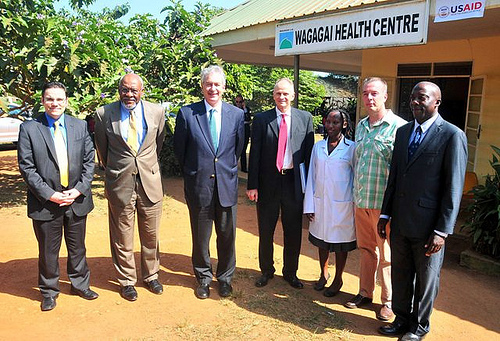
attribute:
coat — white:
[305, 130, 362, 258]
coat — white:
[301, 128, 358, 246]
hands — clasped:
[41, 185, 84, 207]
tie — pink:
[274, 112, 292, 169]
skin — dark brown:
[320, 115, 355, 295]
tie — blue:
[206, 104, 218, 150]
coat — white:
[302, 132, 355, 242]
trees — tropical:
[1, 1, 216, 113]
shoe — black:
[41, 297, 54, 311]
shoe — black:
[70, 286, 98, 298]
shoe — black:
[119, 285, 136, 302]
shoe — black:
[148, 281, 164, 293]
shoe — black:
[194, 282, 209, 298]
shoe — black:
[214, 280, 232, 293]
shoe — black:
[255, 272, 275, 286]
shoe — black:
[281, 274, 302, 286]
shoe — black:
[374, 322, 406, 336]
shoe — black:
[396, 332, 418, 339]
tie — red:
[274, 112, 291, 175]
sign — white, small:
[258, 16, 485, 89]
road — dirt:
[4, 151, 486, 339]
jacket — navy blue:
[168, 94, 249, 214]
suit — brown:
[106, 101, 166, 288]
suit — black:
[19, 115, 96, 300]